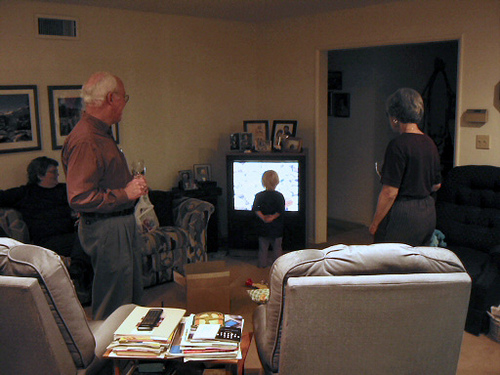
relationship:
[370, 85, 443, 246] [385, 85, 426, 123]
woman has hair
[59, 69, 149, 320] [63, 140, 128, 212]
man has arm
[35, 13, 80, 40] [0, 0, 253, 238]
vent attached to wall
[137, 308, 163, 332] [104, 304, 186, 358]
remote control lying on books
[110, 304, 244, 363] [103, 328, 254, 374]
books stacked on table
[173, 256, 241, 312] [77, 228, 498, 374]
cardboard box laying on floor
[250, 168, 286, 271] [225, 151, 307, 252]
boy standing in front of television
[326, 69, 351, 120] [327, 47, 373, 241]
pictures hanging in hallway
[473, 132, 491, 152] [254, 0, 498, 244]
switch panel attached to wall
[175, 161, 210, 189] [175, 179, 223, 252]
pictures sitting on table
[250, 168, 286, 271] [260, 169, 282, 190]
boy has hair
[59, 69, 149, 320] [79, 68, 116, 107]
man has hair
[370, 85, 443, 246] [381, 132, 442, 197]
woman wearing shirt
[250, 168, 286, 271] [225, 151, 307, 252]
boy watching television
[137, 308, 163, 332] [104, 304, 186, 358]
remote control on top of books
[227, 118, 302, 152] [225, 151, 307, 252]
framed pictures sitting on television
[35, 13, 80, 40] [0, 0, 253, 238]
vent mounted in wall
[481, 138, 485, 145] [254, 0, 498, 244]
light switch on side of wall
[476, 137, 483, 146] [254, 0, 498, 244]
light switch on side of wall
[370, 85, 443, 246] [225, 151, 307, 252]
woman watching television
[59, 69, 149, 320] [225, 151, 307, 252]
man watching television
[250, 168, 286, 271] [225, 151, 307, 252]
boy in front of television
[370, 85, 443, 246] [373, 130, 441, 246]
woman wearing outfit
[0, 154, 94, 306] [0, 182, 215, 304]
person sitting on couch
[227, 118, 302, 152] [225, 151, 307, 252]
framed pictures on top of television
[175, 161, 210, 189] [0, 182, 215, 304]
pictures above couch